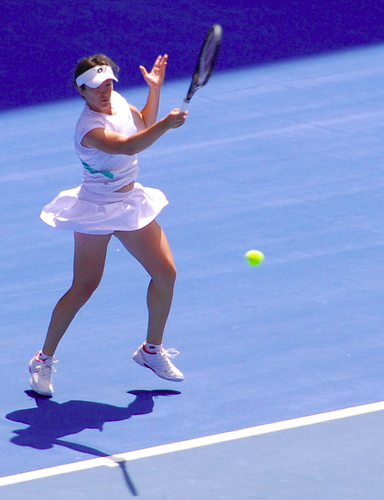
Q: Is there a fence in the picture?
A: No, there are no fences.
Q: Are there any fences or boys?
A: No, there are no fences or boys.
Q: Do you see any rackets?
A: Yes, there is a racket.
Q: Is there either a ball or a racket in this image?
A: Yes, there is a racket.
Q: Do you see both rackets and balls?
A: Yes, there are both a racket and a ball.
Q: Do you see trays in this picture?
A: No, there are no trays.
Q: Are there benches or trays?
A: No, there are no trays or benches.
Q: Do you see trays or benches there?
A: No, there are no trays or benches.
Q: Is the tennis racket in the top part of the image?
A: Yes, the tennis racket is in the top of the image.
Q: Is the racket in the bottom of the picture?
A: No, the racket is in the top of the image.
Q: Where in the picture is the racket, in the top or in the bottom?
A: The racket is in the top of the image.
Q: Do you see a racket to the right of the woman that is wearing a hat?
A: Yes, there is a racket to the right of the woman.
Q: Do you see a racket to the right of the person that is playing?
A: Yes, there is a racket to the right of the woman.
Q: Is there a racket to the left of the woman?
A: No, the racket is to the right of the woman.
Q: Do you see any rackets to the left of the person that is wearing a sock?
A: No, the racket is to the right of the woman.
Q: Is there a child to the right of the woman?
A: No, there is a racket to the right of the woman.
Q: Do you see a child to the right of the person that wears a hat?
A: No, there is a racket to the right of the woman.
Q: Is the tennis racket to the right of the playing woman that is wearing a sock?
A: Yes, the tennis racket is to the right of the woman.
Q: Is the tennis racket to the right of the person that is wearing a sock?
A: Yes, the tennis racket is to the right of the woman.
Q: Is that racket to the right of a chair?
A: No, the racket is to the right of the woman.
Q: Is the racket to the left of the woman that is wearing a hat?
A: No, the racket is to the right of the woman.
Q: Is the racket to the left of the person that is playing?
A: No, the racket is to the right of the woman.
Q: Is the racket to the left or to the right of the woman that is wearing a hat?
A: The racket is to the right of the woman.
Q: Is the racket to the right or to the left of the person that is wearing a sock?
A: The racket is to the right of the woman.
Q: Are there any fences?
A: No, there are no fences.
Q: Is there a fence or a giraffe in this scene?
A: No, there are no fences or giraffes.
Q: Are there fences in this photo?
A: No, there are no fences.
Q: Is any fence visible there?
A: No, there are no fences.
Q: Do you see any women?
A: Yes, there is a woman.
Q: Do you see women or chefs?
A: Yes, there is a woman.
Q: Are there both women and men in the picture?
A: No, there is a woman but no men.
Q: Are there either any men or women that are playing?
A: Yes, the woman is playing.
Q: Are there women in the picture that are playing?
A: Yes, there is a woman that is playing.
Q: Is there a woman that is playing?
A: Yes, there is a woman that is playing.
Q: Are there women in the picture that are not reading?
A: Yes, there is a woman that is playing.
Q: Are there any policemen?
A: No, there are no policemen.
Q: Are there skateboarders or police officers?
A: No, there are no police officers or skateboarders.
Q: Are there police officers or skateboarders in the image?
A: No, there are no police officers or skateboarders.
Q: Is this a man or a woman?
A: This is a woman.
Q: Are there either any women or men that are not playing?
A: No, there is a woman but she is playing.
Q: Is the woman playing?
A: Yes, the woman is playing.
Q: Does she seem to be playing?
A: Yes, the woman is playing.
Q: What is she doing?
A: The woman is playing.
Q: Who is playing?
A: The woman is playing.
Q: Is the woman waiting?
A: No, the woman is playing.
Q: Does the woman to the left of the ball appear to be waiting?
A: No, the woman is playing.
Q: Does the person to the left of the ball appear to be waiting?
A: No, the woman is playing.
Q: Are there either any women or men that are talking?
A: No, there is a woman but she is playing.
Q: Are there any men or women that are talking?
A: No, there is a woman but she is playing.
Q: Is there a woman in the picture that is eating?
A: No, there is a woman but she is playing.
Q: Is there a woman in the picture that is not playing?
A: No, there is a woman but she is playing.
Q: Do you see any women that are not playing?
A: No, there is a woman but she is playing.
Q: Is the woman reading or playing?
A: The woman is playing.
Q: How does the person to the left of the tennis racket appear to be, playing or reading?
A: The woman is playing.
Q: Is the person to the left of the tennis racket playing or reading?
A: The woman is playing.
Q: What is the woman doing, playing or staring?
A: The woman is playing.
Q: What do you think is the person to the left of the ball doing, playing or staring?
A: The woman is playing.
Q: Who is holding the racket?
A: The woman is holding the racket.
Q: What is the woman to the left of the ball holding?
A: The woman is holding the racket.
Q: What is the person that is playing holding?
A: The woman is holding the racket.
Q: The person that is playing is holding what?
A: The woman is holding the racket.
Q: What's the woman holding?
A: The woman is holding the racket.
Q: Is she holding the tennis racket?
A: Yes, the woman is holding the tennis racket.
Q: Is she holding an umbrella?
A: No, the woman is holding the tennis racket.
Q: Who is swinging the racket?
A: The woman is swinging the racket.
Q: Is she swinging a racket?
A: Yes, the woman is swinging a racket.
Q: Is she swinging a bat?
A: No, the woman is swinging a racket.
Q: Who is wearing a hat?
A: The woman is wearing a hat.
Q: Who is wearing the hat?
A: The woman is wearing a hat.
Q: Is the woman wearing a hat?
A: Yes, the woman is wearing a hat.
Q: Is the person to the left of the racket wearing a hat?
A: Yes, the woman is wearing a hat.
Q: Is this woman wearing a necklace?
A: No, the woman is wearing a hat.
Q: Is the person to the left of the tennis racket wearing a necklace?
A: No, the woman is wearing a hat.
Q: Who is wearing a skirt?
A: The woman is wearing a skirt.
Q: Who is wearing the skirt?
A: The woman is wearing a skirt.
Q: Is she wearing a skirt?
A: Yes, the woman is wearing a skirt.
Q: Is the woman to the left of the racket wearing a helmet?
A: No, the woman is wearing a skirt.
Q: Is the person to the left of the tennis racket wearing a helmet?
A: No, the woman is wearing a skirt.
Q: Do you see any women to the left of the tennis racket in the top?
A: Yes, there is a woman to the left of the racket.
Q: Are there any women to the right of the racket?
A: No, the woman is to the left of the racket.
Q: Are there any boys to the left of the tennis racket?
A: No, there is a woman to the left of the tennis racket.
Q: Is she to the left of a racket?
A: Yes, the woman is to the left of a racket.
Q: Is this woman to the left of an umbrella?
A: No, the woman is to the left of a racket.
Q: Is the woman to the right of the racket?
A: No, the woman is to the left of the racket.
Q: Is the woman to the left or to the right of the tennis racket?
A: The woman is to the left of the tennis racket.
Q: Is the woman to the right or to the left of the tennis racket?
A: The woman is to the left of the tennis racket.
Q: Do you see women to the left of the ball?
A: Yes, there is a woman to the left of the ball.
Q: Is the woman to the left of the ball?
A: Yes, the woman is to the left of the ball.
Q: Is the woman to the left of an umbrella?
A: No, the woman is to the left of the ball.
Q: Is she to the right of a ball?
A: No, the woman is to the left of a ball.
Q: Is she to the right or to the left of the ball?
A: The woman is to the left of the ball.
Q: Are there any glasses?
A: No, there are no glasses.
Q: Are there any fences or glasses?
A: No, there are no glasses or fences.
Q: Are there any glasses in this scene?
A: No, there are no glasses.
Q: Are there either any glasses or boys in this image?
A: No, there are no glasses or boys.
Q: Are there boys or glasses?
A: No, there are no glasses or boys.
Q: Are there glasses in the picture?
A: No, there are no glasses.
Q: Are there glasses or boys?
A: No, there are no glasses or boys.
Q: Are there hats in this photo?
A: Yes, there is a hat.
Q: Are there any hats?
A: Yes, there is a hat.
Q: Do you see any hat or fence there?
A: Yes, there is a hat.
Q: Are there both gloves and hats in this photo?
A: No, there is a hat but no gloves.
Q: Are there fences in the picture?
A: No, there are no fences.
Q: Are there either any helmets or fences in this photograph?
A: No, there are no fences or helmets.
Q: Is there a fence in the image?
A: No, there are no fences.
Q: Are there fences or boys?
A: No, there are no fences or boys.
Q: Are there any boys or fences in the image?
A: No, there are no fences or boys.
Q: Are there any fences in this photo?
A: No, there are no fences.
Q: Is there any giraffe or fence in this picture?
A: No, there are no fences or giraffes.